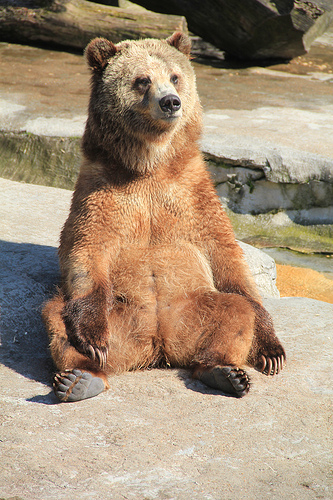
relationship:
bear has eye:
[41, 26, 289, 408] [134, 76, 148, 90]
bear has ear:
[41, 26, 289, 408] [83, 37, 117, 69]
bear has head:
[41, 26, 289, 408] [79, 30, 204, 166]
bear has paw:
[41, 26, 289, 408] [68, 306, 112, 367]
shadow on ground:
[0, 237, 89, 405] [2, 32, 333, 498]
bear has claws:
[41, 26, 289, 408] [88, 343, 97, 357]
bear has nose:
[41, 26, 289, 408] [159, 93, 180, 114]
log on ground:
[0, 1, 192, 65] [2, 32, 333, 498]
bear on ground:
[41, 26, 289, 408] [2, 32, 333, 498]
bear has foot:
[41, 26, 289, 408] [52, 365, 109, 404]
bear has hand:
[41, 26, 289, 408] [68, 306, 112, 367]